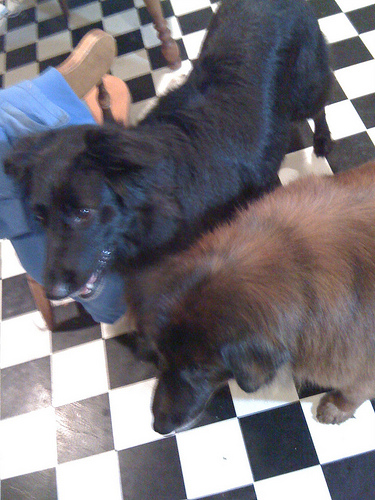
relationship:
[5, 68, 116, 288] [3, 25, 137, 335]
clothing on chair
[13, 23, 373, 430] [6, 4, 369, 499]
dogs on floor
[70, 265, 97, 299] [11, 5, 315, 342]
mouth of dog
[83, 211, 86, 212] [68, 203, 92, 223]
light in eye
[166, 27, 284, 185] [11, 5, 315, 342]
coat on dog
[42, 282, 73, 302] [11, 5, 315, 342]
nose of dog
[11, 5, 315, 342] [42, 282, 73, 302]
dog has nose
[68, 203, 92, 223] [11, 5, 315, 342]
eye of dog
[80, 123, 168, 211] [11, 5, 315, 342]
ear of dog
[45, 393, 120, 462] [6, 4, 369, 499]
tile on floor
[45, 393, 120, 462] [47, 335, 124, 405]
tile next to tile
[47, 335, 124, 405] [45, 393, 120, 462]
tile next to tile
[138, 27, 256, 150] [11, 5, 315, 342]
fur on dog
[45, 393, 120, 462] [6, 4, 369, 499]
box on floor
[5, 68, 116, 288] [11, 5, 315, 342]
clothing behind dog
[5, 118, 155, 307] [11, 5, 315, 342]
head of dog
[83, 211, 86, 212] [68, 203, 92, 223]
light on eye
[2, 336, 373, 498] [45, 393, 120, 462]
floor has tile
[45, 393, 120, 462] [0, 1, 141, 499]
tile on floor